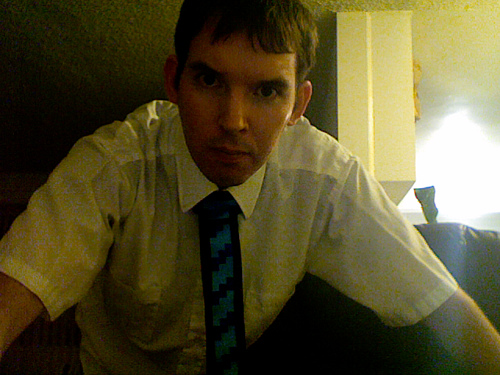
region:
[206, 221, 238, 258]
blue pattern going down tie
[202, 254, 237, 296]
blue pattern going down tie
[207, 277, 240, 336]
blue pattern going down tie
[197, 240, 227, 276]
blue pattern going down tie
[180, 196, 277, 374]
A black and blue tie.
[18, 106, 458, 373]
A white collared shirt with short sleeves.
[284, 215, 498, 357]
a sofa in the background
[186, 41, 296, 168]
A serious facial expression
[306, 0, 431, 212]
a cabinet in the background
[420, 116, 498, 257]
A beam of light on the wall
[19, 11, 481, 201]
A wall in shadow behind the person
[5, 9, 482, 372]
A person leaning over.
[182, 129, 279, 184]
Facial stubble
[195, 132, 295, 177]
A frown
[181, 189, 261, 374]
tie is black and blue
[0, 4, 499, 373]
Man wears a white shirt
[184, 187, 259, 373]
Tie has blue decorations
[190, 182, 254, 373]
Tie is around collar of shirt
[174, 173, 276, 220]
Collar of shirt is white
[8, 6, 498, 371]
Boy if bend forward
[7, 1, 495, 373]
Man has extended arms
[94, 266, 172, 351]
Shirt pocket on left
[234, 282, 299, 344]
Shirt pocket on right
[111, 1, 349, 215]
Man is serious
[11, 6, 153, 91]
Roof of room is white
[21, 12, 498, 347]
a man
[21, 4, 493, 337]
a man leans down with his arms out to the sides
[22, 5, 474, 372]
a man with a serious expression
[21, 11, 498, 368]
the man wears a white shirt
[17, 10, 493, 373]
a man wears a short sleeved white shirt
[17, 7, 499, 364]
a man wears a shirt and tie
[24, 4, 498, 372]
the man has a blue tie on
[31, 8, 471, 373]
the man has short brown hair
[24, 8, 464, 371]
the man has a blue tie with a light blue pattern on it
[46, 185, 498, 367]
a couch is behind the man